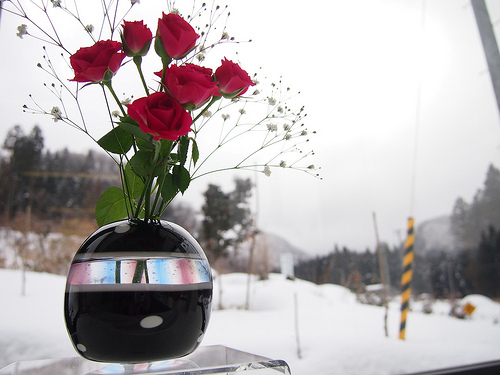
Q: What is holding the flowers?
A: Vase.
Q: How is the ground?
A: Covered in snow.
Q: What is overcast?
A: Sky.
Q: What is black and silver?
A: Vase.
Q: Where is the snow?
A: On the ground.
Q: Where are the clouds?
A: In the sky.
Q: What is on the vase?
A: Flowers.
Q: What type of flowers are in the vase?
A: Roses.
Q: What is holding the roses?
A: Vase.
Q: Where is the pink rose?
A: Vase.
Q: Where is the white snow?
A: Ground.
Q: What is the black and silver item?
A: Vase.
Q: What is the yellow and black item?
A: Pole.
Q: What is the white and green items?
A: Baby's breath.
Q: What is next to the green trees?
A: White snow.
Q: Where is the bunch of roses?
A: In a vase.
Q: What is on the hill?
A: Green trees.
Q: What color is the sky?
A: White.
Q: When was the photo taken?
A: During the day.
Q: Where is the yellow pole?
A: In the snowbank near the street.